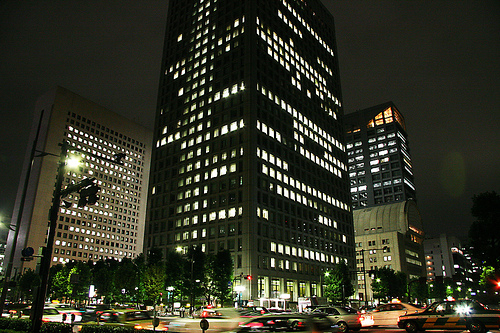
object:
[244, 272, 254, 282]
stop light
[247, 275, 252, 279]
red light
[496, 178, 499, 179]
people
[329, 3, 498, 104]
sky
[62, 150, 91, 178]
light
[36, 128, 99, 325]
metal pole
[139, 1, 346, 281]
windows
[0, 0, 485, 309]
buildings/windows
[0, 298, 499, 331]
cars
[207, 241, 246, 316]
trees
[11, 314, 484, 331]
street